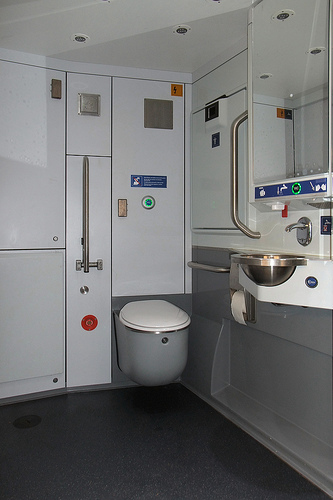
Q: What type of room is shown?
A: It is a bathroom.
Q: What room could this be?
A: It is a bathroom.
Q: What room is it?
A: It is a bathroom.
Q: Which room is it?
A: It is a bathroom.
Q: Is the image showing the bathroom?
A: Yes, it is showing the bathroom.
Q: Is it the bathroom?
A: Yes, it is the bathroom.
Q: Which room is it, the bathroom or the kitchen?
A: It is the bathroom.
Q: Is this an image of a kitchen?
A: No, the picture is showing a bathroom.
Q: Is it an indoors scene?
A: Yes, it is indoors.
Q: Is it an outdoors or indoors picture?
A: It is indoors.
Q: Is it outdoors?
A: No, it is indoors.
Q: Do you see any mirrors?
A: Yes, there is a mirror.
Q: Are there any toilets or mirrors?
A: Yes, there is a mirror.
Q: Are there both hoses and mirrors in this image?
A: No, there is a mirror but no hoses.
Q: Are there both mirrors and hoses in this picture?
A: No, there is a mirror but no hoses.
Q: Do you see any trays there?
A: No, there are no trays.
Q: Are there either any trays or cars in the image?
A: No, there are no trays or cars.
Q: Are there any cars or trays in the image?
A: No, there are no trays or cars.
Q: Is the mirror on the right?
A: Yes, the mirror is on the right of the image.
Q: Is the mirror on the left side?
A: No, the mirror is on the right of the image.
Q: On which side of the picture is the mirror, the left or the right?
A: The mirror is on the right of the image.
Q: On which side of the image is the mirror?
A: The mirror is on the right of the image.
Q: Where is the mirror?
A: The mirror is in the bathroom.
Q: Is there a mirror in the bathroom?
A: Yes, there is a mirror in the bathroom.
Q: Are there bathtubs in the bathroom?
A: No, there is a mirror in the bathroom.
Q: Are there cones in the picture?
A: No, there are no cones.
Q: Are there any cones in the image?
A: No, there are no cones.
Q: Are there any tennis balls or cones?
A: No, there are no cones or tennis balls.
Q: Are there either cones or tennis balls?
A: No, there are no cones or tennis balls.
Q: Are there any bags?
A: No, there are no bags.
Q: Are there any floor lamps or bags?
A: No, there are no bags or floor lamps.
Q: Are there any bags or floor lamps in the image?
A: No, there are no bags or floor lamps.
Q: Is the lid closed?
A: Yes, the lid is closed.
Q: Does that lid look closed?
A: Yes, the lid is closed.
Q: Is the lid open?
A: No, the lid is closed.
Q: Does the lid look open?
A: No, the lid is closed.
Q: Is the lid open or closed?
A: The lid is closed.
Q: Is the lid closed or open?
A: The lid is closed.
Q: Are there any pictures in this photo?
A: No, there are no pictures.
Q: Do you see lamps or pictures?
A: No, there are no pictures or lamps.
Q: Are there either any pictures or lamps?
A: No, there are no pictures or lamps.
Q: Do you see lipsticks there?
A: No, there are no lipsticks.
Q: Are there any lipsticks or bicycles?
A: No, there are no lipsticks or bicycles.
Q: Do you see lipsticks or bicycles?
A: No, there are no lipsticks or bicycles.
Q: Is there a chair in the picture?
A: No, there are no chairs.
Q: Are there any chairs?
A: No, there are no chairs.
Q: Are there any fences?
A: No, there are no fences.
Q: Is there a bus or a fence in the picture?
A: No, there are no fences or buses.